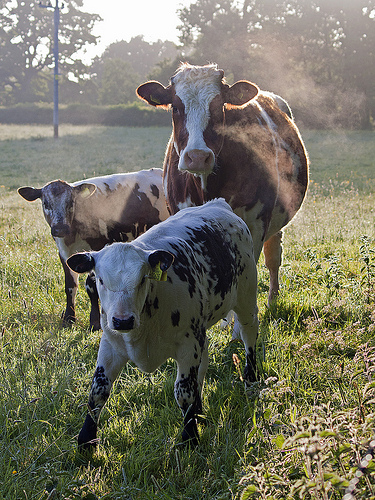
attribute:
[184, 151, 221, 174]
nose — pink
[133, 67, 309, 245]
cow — large, brown markings, white markings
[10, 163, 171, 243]
cow — large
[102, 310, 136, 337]
nose — black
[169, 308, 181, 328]
spot — black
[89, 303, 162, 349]
nose — black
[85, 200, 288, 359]
cow — white, speckles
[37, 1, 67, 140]
pole — light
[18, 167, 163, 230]
cow — white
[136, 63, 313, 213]
cow — white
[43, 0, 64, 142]
pole — tall, power, utility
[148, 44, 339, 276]
cow — large, brown and white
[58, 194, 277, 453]
cow — white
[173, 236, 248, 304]
spot — black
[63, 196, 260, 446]
calf — black and white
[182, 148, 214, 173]
nose — pink, cow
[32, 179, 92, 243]
face — white speckles, brown speckles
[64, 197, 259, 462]
cow — white, black speckles, small, black and white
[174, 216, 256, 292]
speckles — black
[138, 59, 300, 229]
cow — brown, white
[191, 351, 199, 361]
spot — black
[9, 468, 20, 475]
flower — tiny, yellow